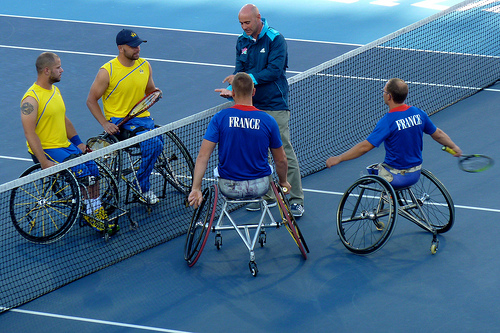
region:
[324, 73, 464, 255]
a man in a wheelchair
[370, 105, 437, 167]
man wearing a blue shirt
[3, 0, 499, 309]
a black and white net on a tennis court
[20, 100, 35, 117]
a black tatto on man's arm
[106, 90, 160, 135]
man holding a red tennis racket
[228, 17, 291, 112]
man wearing a blue windbraker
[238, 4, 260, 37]
a bald man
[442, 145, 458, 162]
yellow handle of a tennis racket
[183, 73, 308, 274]
man holding the side of a wheelchair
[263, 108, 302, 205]
man wearing tan pants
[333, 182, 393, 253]
tires on a wheelchair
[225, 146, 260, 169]
blue shirt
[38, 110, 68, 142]
yellow shirt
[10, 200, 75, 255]
a net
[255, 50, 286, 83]
a blue jacket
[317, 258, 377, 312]
shadow on the court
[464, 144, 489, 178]
a tennis racket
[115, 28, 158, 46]
man is wearing a hat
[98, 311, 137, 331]
white line on the court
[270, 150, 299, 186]
mans arm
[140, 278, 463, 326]
The ground is made of concrete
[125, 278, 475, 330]
The ground is the color blue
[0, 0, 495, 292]
The men are playing tennis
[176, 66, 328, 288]
The man is sitting in a wheel chair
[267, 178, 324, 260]
The wheel of the wheel chair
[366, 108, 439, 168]
The man is wearing a blue shirt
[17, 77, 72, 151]
The man is wearing a yellow shirt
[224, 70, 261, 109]
The head of the man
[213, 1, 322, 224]
The man is talking to the group of men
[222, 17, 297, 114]
The man is wearing a jacket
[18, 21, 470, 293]
people at the tennis court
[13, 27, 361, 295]
men on wheel chairs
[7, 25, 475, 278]
these men are all physically challenged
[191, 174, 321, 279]
this man has red wheels on his chair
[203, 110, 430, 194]
both these player represent France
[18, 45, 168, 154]
these fellows are wearing yellow shirts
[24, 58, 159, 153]
the shirts are sleeveless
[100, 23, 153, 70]
this man is wearing a blue cap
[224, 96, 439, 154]
these two fellows have red trim on their shirts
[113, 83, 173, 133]
this man is holding a red raquette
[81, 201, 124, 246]
this man appears to have yellow sneakers on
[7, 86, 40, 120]
this man has a tattoo